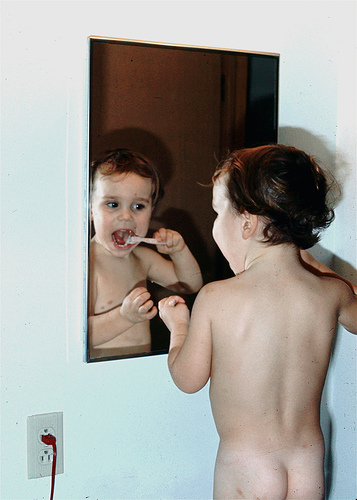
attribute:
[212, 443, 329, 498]
butt — person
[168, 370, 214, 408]
elbow — person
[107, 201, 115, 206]
eye — bright, clear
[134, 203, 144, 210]
eye — bright, clear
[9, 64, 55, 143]
wall — white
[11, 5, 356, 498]
walls — blue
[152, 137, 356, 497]
toddler — naked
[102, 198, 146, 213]
eyes — brown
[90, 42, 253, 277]
door — brown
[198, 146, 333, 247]
hair — dark, smooth, curly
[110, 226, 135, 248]
mouth — open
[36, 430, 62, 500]
plug — red